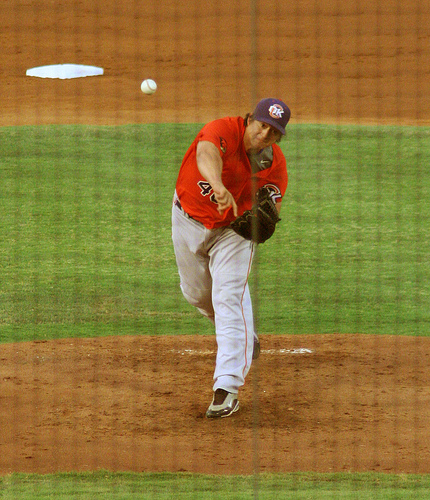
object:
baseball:
[140, 77, 158, 95]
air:
[105, 34, 202, 111]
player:
[170, 95, 294, 420]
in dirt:
[29, 343, 388, 455]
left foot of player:
[205, 380, 240, 420]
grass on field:
[0, 121, 430, 343]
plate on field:
[24, 60, 105, 80]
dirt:
[0, 0, 430, 125]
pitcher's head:
[247, 96, 292, 150]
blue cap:
[251, 97, 292, 136]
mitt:
[229, 186, 281, 245]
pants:
[170, 187, 258, 395]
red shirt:
[174, 114, 289, 230]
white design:
[268, 103, 285, 120]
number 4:
[197, 180, 213, 197]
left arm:
[254, 157, 289, 217]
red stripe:
[240, 243, 255, 378]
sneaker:
[204, 388, 240, 420]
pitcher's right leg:
[171, 189, 215, 326]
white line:
[169, 347, 313, 354]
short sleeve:
[197, 116, 245, 157]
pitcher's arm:
[195, 116, 239, 220]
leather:
[228, 182, 281, 246]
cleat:
[253, 334, 260, 359]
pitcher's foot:
[252, 331, 262, 361]